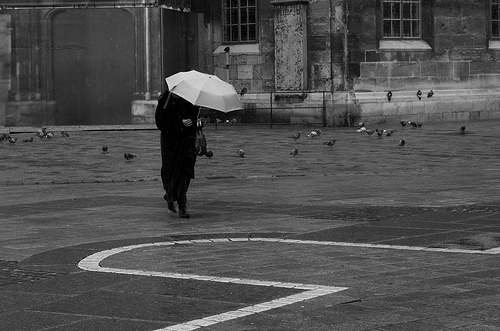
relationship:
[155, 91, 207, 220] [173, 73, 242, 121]
person holding umbrella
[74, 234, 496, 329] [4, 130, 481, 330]
line on ground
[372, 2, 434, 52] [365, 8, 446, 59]
window set into wall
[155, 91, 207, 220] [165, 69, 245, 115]
person walking umberella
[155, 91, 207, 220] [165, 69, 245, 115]
person holding umberella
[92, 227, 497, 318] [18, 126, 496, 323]
white line set into road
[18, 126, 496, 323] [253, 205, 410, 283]
road with stones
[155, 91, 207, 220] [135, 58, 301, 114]
person with umbrella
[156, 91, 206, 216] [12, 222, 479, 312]
person walking rain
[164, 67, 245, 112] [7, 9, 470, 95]
umbrella avoid rain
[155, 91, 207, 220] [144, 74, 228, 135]
person avoid wet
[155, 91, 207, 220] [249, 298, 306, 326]
person avoid bird poop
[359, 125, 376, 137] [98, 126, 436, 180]
pigeons begging food